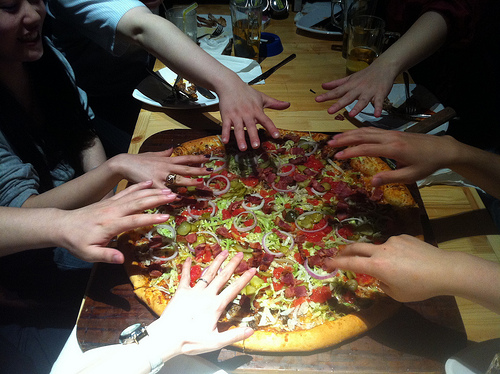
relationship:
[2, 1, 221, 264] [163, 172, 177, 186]
girl wearing ring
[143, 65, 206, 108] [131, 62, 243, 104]
silverware on plates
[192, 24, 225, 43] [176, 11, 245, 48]
silverware on plates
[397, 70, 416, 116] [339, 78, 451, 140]
silverware on plates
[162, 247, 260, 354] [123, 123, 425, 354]
hands over pizza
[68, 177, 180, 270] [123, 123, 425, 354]
hands over pizza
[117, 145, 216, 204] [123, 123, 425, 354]
hands over pizza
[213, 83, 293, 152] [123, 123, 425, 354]
hands over pizza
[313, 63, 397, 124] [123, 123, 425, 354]
hands over pizza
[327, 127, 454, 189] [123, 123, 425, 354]
hands over pizza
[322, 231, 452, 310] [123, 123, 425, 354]
hands over pizza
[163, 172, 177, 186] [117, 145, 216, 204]
ring on hands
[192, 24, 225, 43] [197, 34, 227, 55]
silverware on napkin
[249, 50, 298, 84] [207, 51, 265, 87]
knife on napkin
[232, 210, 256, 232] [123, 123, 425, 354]
onion on pizza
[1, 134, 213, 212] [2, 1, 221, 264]
arm of girl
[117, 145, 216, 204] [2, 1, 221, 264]
hands of girl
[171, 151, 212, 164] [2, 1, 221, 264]
finger of girl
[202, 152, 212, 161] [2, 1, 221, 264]
fingernails of girl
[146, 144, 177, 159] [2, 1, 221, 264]
thumb of girl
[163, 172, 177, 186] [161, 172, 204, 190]
ring on finger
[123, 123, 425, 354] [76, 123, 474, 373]
pizza on tray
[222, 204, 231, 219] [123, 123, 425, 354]
tomato on pizza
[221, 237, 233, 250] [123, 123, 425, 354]
lettuce on pizza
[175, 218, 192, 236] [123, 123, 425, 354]
pickel on pizza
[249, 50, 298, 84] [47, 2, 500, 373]
knife on table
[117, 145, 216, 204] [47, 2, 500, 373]
hands on table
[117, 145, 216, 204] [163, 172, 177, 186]
hands wearing ring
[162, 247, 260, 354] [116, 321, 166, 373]
hands wearing watch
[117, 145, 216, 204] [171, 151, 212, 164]
hands with finger